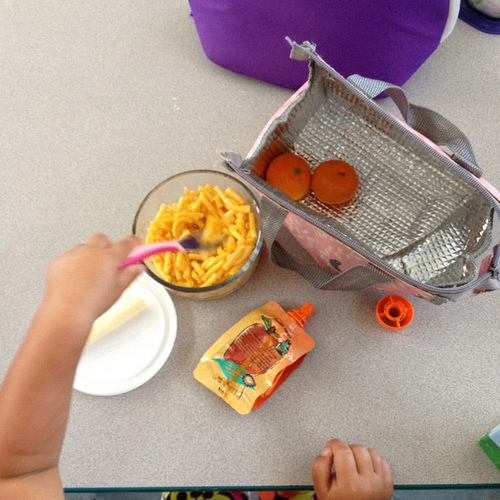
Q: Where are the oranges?
A: In the bag.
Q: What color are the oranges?
A: Orange.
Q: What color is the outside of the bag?
A: Pink and white.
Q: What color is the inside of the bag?
A: Silver.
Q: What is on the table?
A: The bag.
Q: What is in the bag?
A: Oranges.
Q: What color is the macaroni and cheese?
A: Yellow.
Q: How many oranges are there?
A: Two.